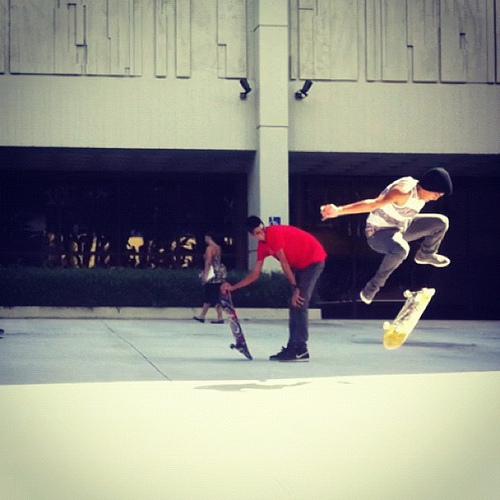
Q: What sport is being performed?
A: Skateboarding.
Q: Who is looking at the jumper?
A: The boy with the red shirt.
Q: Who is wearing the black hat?
A: The boy jumping.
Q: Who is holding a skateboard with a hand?
A: The boy with the red shirt.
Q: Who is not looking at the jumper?
A: The woman in the back.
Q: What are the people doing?
A: Skateboarding.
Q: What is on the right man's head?
A: Hat.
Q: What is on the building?
A: Speakers.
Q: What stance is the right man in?
A: Jumping.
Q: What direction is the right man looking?
A: Down.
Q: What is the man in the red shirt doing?
A: Watching.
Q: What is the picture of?
A: The picture is of a guy jumping.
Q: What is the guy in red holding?
A: The guy in the red is holding a skateboard.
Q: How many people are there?
A: Three.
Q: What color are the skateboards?
A: Yellow, white and black.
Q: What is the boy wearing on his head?
A: A hat.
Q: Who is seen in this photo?
A: Boys and a woman.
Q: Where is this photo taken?
A: In front of a building.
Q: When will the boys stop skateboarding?
A: After they get tired.